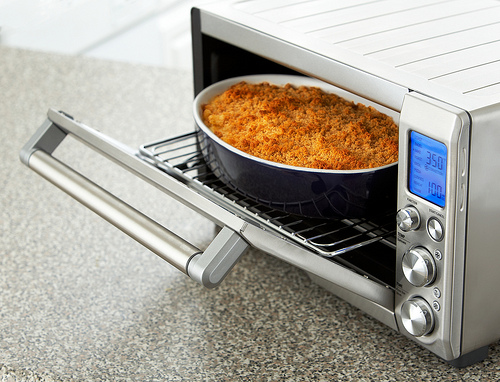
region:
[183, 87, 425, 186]
a dish of food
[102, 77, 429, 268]
a dish of food in a oven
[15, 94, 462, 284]
a small silver oven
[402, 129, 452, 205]
blue and black digital readings on a oven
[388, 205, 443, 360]
silver control knobs on a oven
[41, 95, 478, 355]
a oven on a granite counter top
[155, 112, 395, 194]
a black and white cooking dish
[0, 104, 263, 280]
a silver oven door handle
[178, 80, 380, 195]
a caserole in a dish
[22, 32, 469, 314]
a oven with a dish of food in it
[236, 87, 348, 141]
this is fried rice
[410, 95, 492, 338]
this is a microwave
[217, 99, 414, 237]
the microwave is open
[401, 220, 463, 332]
the microwave is metallic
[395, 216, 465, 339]
the microwave is silvery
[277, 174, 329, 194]
the bowl is purple in color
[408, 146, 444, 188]
the light is on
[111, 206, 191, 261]
the holder is big in size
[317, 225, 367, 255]
the grill is metallic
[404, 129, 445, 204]
a blue gauge on the oven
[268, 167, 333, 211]
a dark blue ceramic dish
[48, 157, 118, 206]
a long silver handle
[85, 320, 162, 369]
a multicolored granite surface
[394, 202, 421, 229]
the silver temperature control knob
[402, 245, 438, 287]
a larger silver selection knob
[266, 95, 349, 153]
a delicious baked casserole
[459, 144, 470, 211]
small indentations on the edge of the oven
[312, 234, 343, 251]
a wire metal rack in the overn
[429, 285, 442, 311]
small silver push buttons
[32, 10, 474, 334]
a toaster oven sitting on a counter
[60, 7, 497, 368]
the toaster oven is silver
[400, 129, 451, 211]
the information panel is blue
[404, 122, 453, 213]
the information panel says 350 and 100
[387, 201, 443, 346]
three silver dials on the toaster oven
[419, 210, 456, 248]
a circular silver button on the toaster oven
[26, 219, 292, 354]
gray countertop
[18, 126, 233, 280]
silver handle of the toaster oven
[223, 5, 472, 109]
grooved top of toaster oven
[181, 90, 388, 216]
bowl of food inside toaster oven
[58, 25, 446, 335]
a silver toaster oven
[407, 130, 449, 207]
the oven has a blue information panel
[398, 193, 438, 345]
the oven has three silver dials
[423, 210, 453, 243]
the oven has a silver button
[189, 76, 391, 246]
blue bowl inside the oven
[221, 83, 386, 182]
toasted food inside the bowl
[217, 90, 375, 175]
the food looks crispy and brown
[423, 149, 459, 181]
the temperature of the oven is 350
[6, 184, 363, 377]
gray granite counter top